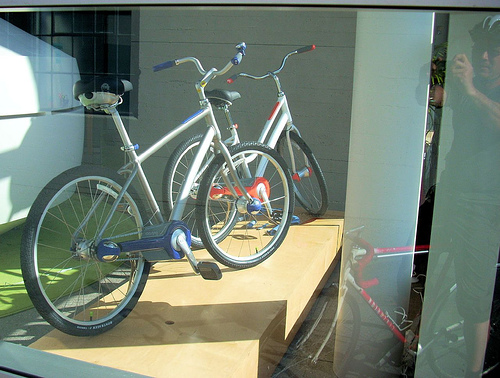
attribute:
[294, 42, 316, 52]
grip — red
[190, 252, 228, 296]
peddle — black, plastic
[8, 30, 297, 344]
bike — gray, blue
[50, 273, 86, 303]
spoke — Silver 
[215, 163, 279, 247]
spoke — Silver 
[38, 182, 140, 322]
spoke — Silver 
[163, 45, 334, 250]
bicycle — red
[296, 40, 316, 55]
bike grip — red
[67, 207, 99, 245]
spoke — Silver 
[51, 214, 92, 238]
spoke — silver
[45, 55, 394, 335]
bicycle — blue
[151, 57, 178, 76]
grip — blue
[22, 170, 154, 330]
tire — black, rubber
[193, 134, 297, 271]
tire — black, rubber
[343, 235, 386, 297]
bike grip — red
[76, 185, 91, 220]
spoke — Silver 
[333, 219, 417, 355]
bicycle — red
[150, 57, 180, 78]
bike grip — blue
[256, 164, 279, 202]
spoke — silver